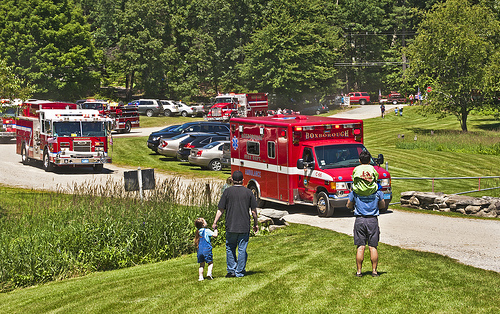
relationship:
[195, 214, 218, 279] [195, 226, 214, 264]
child wearing overalls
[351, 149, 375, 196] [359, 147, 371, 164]
girl with hair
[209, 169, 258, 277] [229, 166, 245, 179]
spectators wearing hat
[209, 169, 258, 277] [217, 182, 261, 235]
spectators wearing pullover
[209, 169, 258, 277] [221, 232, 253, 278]
spectators wearing jeans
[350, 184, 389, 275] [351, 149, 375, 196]
man carrying girl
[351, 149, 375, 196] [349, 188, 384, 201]
girl on shoulders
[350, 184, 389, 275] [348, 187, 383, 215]
man wearing pullover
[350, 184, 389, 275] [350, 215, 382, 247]
man wearing shorts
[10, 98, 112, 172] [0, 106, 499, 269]
truck driving up road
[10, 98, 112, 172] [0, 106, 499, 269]
truck up road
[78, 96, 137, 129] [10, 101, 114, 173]
fire truck behind fire rescue truck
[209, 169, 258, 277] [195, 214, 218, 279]
spectators with child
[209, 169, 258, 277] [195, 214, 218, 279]
spectators walking with child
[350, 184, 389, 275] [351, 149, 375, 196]
man has girl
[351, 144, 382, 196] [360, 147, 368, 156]
girl has ponytail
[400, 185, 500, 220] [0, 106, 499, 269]
wall next to road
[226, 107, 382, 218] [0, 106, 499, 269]
vehicle on road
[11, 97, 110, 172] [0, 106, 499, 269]
truck on road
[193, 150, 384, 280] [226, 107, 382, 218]
spectators watching vehicle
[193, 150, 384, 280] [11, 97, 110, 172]
spectators watching truck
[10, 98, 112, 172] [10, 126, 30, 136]
truck has stripe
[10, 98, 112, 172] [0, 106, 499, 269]
truck in road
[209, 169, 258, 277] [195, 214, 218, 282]
spectators holds child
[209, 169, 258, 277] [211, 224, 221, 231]
spectators holds with hand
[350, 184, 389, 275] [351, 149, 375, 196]
man carries girl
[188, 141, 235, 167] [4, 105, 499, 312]
car on grass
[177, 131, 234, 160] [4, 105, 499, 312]
car on grass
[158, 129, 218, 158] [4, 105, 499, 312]
car on grass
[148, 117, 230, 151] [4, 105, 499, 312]
car on grass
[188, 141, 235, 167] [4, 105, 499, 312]
car parking on grass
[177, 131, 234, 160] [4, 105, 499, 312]
car parking on grass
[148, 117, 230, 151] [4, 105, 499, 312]
car parking on grass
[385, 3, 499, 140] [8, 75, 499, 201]
tree in middle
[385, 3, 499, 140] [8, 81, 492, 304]
tree middle of field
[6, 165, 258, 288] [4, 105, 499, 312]
weeds side of grass